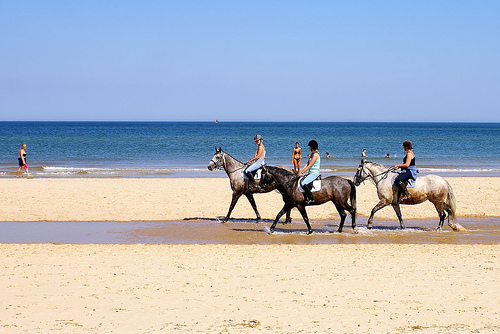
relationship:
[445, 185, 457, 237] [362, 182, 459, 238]
long tail of horse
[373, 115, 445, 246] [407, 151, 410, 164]
woman wears a black top